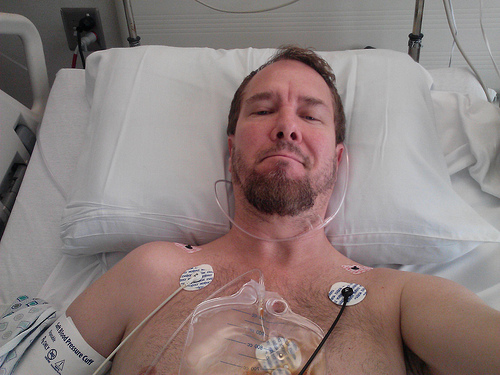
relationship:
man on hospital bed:
[25, 56, 499, 374] [2, 10, 500, 371]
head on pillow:
[234, 55, 332, 216] [85, 43, 470, 267]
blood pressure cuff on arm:
[16, 317, 111, 373] [17, 239, 183, 374]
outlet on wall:
[63, 9, 101, 49] [3, 1, 499, 101]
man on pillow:
[25, 56, 499, 374] [85, 43, 470, 267]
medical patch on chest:
[327, 283, 368, 309] [110, 241, 408, 374]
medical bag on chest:
[195, 283, 328, 373] [110, 241, 408, 374]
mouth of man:
[256, 148, 308, 176] [25, 56, 499, 374]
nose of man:
[269, 101, 305, 144] [25, 56, 499, 374]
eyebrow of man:
[246, 89, 274, 102] [25, 56, 499, 374]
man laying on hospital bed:
[25, 56, 499, 374] [2, 10, 500, 371]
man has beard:
[25, 56, 499, 374] [228, 147, 339, 217]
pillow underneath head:
[85, 43, 470, 267] [234, 55, 332, 216]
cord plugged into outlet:
[68, 49, 82, 70] [63, 9, 101, 49]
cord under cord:
[68, 49, 82, 70] [76, 15, 93, 34]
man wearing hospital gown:
[25, 56, 499, 374] [2, 291, 51, 363]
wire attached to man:
[281, 287, 367, 374] [25, 56, 499, 374]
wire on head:
[215, 141, 349, 243] [234, 55, 332, 216]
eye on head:
[300, 107, 332, 127] [234, 55, 332, 216]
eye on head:
[247, 102, 278, 118] [234, 55, 332, 216]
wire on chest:
[281, 287, 367, 374] [110, 241, 408, 374]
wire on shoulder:
[177, 234, 200, 254] [150, 229, 232, 270]